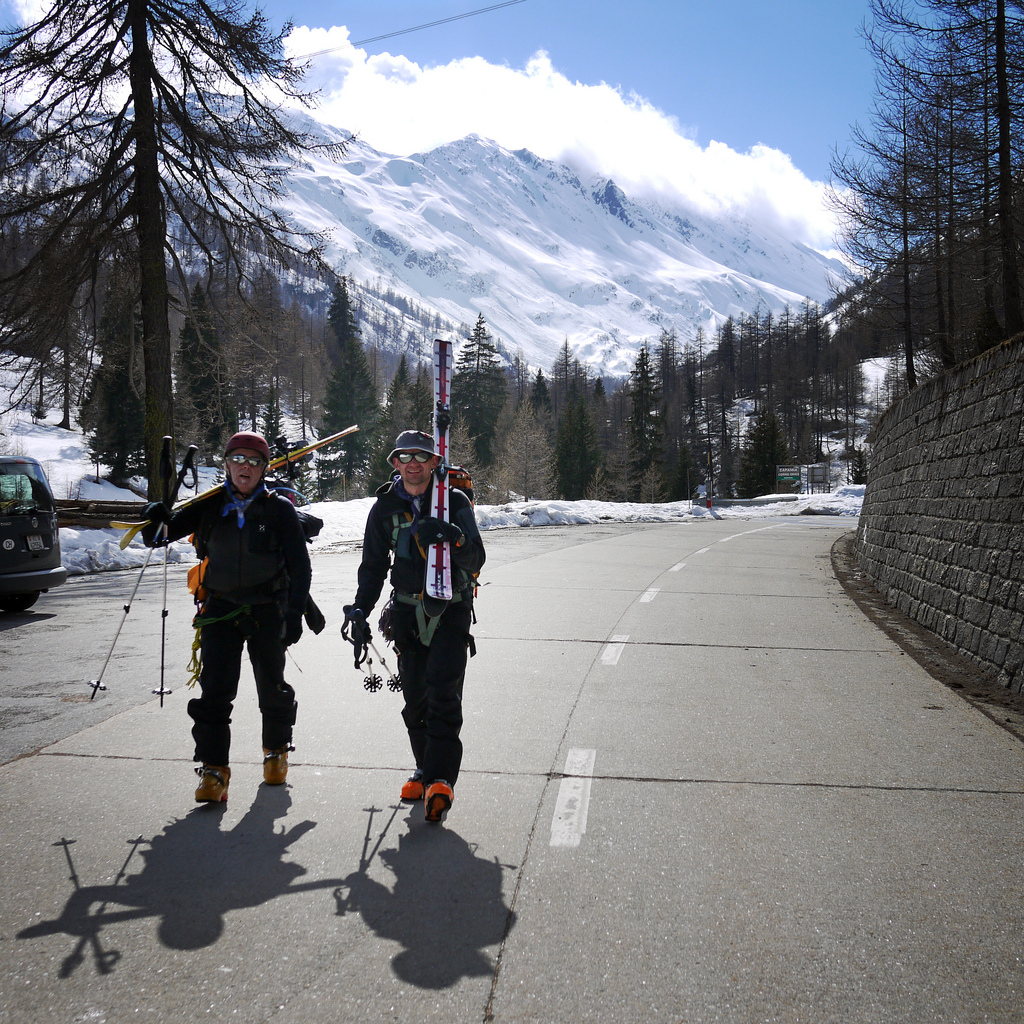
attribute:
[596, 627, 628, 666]
stripe — white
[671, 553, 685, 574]
stripe — white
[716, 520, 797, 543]
stripe — white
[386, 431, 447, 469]
hat — gray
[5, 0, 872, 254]
clouds — white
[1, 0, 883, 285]
clouds — white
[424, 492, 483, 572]
arm — man's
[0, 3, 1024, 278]
sky — blue